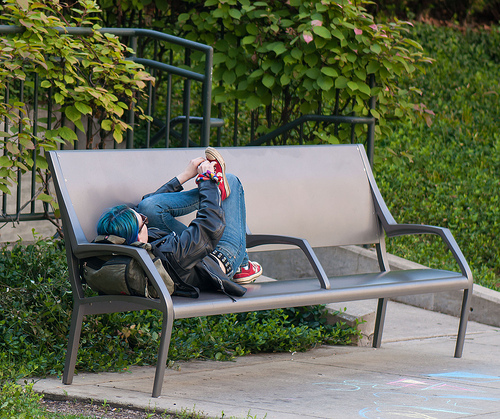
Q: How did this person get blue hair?
A: She dyed it.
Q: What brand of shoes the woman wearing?
A: Converse.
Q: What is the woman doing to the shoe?
A: Tying it.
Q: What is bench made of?
A: Metal.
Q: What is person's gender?
A: Female.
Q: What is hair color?
A: Blue.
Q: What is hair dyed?
A: Blue.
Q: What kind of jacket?
A: Leather.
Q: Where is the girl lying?
A: Bench.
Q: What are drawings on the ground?
A: Chalk.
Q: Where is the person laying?
A: On a bench.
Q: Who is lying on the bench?
A: Girl with blue hair.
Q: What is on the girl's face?
A: Eye glasses.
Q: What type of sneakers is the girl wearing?
A: Red and white.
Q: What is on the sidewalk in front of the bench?
A: Sidewalk art with chalk.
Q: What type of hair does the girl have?
A: Dyed blue hair.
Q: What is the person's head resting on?
A: Backpack.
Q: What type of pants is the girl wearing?
A: Blue jeans.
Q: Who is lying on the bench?
A: A female.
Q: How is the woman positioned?
A: Lying down.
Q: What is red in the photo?
A: Sneakers.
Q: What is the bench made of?
A: Metal.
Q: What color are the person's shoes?
A: Red.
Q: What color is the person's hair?
A: Blue.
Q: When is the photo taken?
A: Daytime.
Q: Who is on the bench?
A: Female.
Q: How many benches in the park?
A: One.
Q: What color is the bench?
A: Grey.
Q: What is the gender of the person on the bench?
A: Female.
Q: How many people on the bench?
A: One.